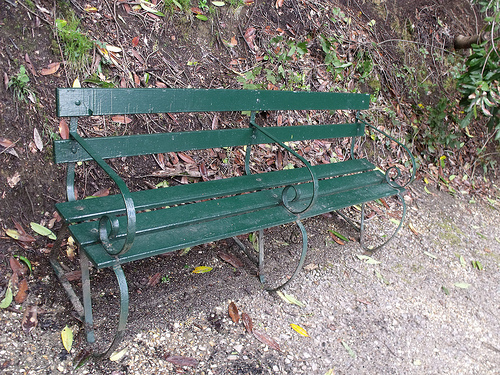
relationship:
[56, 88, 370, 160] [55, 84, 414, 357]
back of bench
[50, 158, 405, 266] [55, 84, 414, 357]
seat of bench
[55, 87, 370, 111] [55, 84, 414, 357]
rail of bench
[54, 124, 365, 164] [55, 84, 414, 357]
rail of bench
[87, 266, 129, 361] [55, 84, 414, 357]
support of bench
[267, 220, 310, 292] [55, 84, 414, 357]
support of bench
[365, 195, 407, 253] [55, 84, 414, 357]
support of bench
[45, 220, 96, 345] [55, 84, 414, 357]
support of bench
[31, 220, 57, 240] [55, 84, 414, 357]
leaf behind bench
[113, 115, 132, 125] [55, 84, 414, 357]
leaf behind bench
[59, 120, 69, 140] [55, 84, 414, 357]
leaf behind bench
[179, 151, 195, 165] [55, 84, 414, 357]
leaf behind bench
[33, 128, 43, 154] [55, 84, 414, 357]
leaf behind bench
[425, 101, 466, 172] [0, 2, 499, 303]
plant in dirt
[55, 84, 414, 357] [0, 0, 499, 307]
bench near hill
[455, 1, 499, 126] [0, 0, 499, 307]
branch on hill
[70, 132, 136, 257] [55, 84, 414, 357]
armrest on bench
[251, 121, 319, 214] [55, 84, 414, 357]
armrest on bench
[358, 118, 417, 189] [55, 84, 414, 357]
armrest on bench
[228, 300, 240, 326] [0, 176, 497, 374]
leaf on ground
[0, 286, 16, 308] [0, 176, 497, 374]
leaf on ground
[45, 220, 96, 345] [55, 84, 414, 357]
support on bench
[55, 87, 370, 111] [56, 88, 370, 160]
rail on back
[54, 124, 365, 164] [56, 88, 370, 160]
rail on back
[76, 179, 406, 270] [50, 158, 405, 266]
slat on seat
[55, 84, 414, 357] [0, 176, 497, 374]
bench on ground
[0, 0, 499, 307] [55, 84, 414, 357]
hill behind bench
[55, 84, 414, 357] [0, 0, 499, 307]
bench on side of hill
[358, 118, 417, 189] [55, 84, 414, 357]
armrest of bench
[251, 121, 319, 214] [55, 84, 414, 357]
armrest of bench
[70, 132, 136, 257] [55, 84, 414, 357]
armrest of bench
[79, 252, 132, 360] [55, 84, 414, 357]
leg of bench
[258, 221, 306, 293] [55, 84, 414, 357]
leg of bench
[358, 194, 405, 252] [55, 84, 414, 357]
leg of bench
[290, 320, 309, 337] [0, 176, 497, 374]
leaf on ground